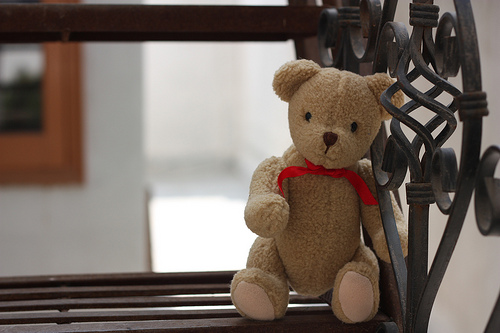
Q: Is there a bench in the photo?
A: Yes, there is a bench.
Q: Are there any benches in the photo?
A: Yes, there is a bench.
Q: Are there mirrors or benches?
A: Yes, there is a bench.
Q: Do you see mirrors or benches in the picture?
A: Yes, there is a bench.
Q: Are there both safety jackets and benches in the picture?
A: No, there is a bench but no safety jackets.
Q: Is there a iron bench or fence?
A: Yes, there is an iron bench.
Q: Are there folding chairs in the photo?
A: No, there are no folding chairs.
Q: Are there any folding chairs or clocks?
A: No, there are no folding chairs or clocks.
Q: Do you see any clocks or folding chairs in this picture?
A: No, there are no folding chairs or clocks.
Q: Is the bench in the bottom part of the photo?
A: Yes, the bench is in the bottom of the image.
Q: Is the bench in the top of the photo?
A: No, the bench is in the bottom of the image.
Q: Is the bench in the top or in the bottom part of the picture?
A: The bench is in the bottom of the image.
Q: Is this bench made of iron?
A: Yes, the bench is made of iron.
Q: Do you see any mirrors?
A: No, there are no mirrors.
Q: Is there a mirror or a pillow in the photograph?
A: No, there are no mirrors or pillows.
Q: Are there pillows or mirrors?
A: No, there are no mirrors or pillows.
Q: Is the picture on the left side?
A: Yes, the picture is on the left of the image.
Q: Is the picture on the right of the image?
A: No, the picture is on the left of the image.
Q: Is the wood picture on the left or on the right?
A: The picture is on the left of the image.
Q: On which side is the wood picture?
A: The picture is on the left of the image.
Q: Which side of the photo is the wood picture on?
A: The picture is on the left of the image.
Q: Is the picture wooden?
A: Yes, the picture is wooden.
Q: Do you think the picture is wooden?
A: Yes, the picture is wooden.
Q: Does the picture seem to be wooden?
A: Yes, the picture is wooden.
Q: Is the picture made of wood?
A: Yes, the picture is made of wood.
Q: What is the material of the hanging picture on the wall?
A: The picture is made of wood.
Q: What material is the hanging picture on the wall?
A: The picture is made of wood.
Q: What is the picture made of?
A: The picture is made of wood.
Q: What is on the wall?
A: The picture is on the wall.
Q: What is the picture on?
A: The picture is on the wall.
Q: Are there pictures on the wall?
A: Yes, there is a picture on the wall.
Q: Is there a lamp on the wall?
A: No, there is a picture on the wall.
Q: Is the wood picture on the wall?
A: Yes, the picture is on the wall.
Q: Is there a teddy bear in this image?
A: Yes, there is a teddy bear.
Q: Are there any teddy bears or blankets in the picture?
A: Yes, there is a teddy bear.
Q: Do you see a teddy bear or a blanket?
A: Yes, there is a teddy bear.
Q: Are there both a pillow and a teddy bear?
A: No, there is a teddy bear but no pillows.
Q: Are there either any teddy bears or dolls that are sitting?
A: Yes, the teddy bear is sitting.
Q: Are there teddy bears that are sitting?
A: Yes, there is a teddy bear that is sitting.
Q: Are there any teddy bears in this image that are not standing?
A: Yes, there is a teddy bear that is sitting.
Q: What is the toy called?
A: The toy is a teddy bear.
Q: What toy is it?
A: The toy is a teddy bear.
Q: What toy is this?
A: This is a teddy bear.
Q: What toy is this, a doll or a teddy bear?
A: This is a teddy bear.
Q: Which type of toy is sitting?
A: The toy is a teddy bear.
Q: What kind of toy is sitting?
A: The toy is a teddy bear.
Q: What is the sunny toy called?
A: The toy is a teddy bear.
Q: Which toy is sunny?
A: The toy is a teddy bear.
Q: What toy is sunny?
A: The toy is a teddy bear.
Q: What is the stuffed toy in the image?
A: The toy is a teddy bear.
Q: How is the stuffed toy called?
A: The toy is a teddy bear.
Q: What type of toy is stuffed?
A: The toy is a teddy bear.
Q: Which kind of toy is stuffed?
A: The toy is a teddy bear.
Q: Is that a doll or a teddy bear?
A: That is a teddy bear.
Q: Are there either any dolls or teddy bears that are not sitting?
A: No, there is a teddy bear but it is sitting.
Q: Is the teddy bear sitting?
A: Yes, the teddy bear is sitting.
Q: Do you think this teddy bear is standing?
A: No, the teddy bear is sitting.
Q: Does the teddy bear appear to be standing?
A: No, the teddy bear is sitting.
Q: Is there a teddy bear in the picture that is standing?
A: No, there is a teddy bear but it is sitting.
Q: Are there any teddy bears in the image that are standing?
A: No, there is a teddy bear but it is sitting.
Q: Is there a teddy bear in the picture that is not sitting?
A: No, there is a teddy bear but it is sitting.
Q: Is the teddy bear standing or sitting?
A: The teddy bear is sitting.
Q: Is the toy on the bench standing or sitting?
A: The teddy bear is sitting.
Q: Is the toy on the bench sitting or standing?
A: The teddy bear is sitting.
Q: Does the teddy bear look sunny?
A: Yes, the teddy bear is sunny.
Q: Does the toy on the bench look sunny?
A: Yes, the teddy bear is sunny.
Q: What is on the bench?
A: The teddy bear is on the bench.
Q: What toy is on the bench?
A: The toy is a teddy bear.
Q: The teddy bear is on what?
A: The teddy bear is on the bench.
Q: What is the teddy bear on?
A: The teddy bear is on the bench.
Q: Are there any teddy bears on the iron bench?
A: Yes, there is a teddy bear on the bench.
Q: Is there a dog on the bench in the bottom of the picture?
A: No, there is a teddy bear on the bench.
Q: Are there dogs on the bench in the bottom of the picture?
A: No, there is a teddy bear on the bench.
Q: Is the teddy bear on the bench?
A: Yes, the teddy bear is on the bench.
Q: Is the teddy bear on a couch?
A: No, the teddy bear is on the bench.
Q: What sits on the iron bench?
A: The teddy bear sits on the bench.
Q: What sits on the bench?
A: The teddy bear sits on the bench.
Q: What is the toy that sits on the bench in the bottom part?
A: The toy is a teddy bear.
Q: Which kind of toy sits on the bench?
A: The toy is a teddy bear.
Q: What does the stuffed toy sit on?
A: The teddy bear sits on the bench.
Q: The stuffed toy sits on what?
A: The teddy bear sits on the bench.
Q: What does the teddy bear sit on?
A: The teddy bear sits on the bench.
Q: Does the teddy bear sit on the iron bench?
A: Yes, the teddy bear sits on the bench.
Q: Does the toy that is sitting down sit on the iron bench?
A: Yes, the teddy bear sits on the bench.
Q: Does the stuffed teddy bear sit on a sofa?
A: No, the teddy bear sits on the bench.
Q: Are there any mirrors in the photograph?
A: No, there are no mirrors.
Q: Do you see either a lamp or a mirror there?
A: No, there are no mirrors or lamps.